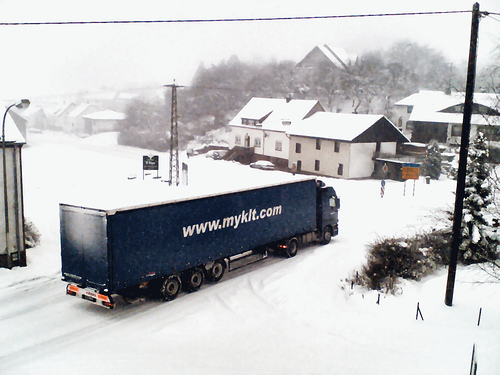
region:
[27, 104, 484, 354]
snow covered road into town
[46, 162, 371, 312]
a dark blue commercial truck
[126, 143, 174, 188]
a black sign on ground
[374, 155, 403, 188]
a red and white sign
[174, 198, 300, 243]
a company website url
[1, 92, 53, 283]
a very tall street light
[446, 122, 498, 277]
a tall pine tree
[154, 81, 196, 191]
a wood telephone post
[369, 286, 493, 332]
a few sign posts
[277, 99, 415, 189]
a simple white building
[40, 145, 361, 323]
Truck is driving in snow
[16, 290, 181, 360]
Truck is leaving behind snow tracks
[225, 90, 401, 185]
Houses is in the background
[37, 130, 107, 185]
The ground is covered in snow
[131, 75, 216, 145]
Trees are in the background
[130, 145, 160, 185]
Dark colored sign is in the background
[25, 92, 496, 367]
Photo was taken in the daytime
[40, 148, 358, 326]
The truck is dark blue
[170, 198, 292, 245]
Truck has white words on the side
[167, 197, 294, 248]
Website on the side of truck says "www.myklt.com"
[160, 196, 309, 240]
truck says myklt.com on the side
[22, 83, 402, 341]
large semi truck driving in the snow.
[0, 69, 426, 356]
semi truck driving in the snow.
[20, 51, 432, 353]
big semi truck driving in the snow.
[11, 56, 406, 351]
huge semi truck driving in the snow.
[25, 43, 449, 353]
long semi truck driving in the snow.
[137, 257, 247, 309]
wheels of a semi truck.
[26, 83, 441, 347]
large semi truck driving on a cold day.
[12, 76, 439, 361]
semi truck driving on a cold day.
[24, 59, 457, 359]
full size semi truck driving on cold day.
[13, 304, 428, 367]
patch of snow on ground.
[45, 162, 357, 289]
truck is long and blue